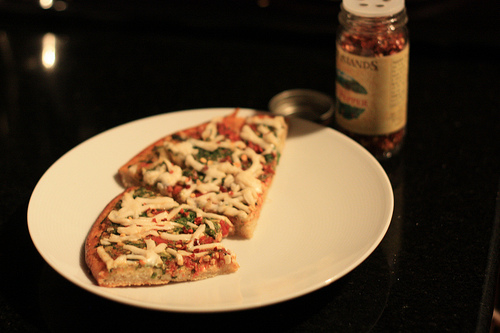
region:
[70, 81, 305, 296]
two small slices of pizza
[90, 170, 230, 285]
shredded cheese on top of pizza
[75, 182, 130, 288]
curved and narrow crust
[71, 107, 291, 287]
one slice larger than the other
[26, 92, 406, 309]
two slices within one plate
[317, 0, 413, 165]
small container of red condiment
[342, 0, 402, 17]
white covering with round holes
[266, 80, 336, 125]
condiment lid in back of plate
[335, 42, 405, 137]
writing on paper label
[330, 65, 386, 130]
two semicircles on front of bottle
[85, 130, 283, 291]
pizza is in plate.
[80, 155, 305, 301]
two piece of pizza.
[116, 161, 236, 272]
cheese is white color.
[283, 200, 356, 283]
plate is white color.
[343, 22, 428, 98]
one bottle is seen.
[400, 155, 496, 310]
table is black color.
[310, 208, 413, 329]
plate is in table.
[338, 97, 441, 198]
bottle is in table.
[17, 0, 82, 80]
light reflection on table.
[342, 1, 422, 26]
white cover of bottle.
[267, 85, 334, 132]
Cover for small spice container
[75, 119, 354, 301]
Two pieces of pizza in the middle of a white plate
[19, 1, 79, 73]
Light reflected off black surface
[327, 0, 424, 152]
Small plastic spice container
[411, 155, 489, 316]
Solid black surface under plate and spice dispenser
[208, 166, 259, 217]
White cheese on top of slice of pizza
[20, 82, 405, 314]
White round shaped plate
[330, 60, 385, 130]
Label on side of spice container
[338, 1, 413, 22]
Slotted cover on top of spice container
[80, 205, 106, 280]
Brown outer edge of crust on piece of pizza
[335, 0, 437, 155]
hot peppers in clear jar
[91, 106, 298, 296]
two slices of pizza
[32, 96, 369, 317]
two pieces of pizza on white plate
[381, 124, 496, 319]
black tabletop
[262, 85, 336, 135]
silver cover to spice jar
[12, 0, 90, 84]
reflection of light on table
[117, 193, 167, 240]
white unmelted cheese on pizza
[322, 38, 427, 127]
yellow label around pepper jar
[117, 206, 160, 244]
white mozzarella cheese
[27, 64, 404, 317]
white plate on black table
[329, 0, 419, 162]
jar of spice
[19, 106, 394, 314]
plain white plate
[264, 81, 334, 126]
lid of the spice jar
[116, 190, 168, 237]
shredded cheese on top of pizza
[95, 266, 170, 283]
bottom of pizza crust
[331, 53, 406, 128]
label on spice jar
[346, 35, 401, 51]
crushed red pepper flakes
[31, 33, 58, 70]
reflection of a light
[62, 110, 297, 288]
part of a meal